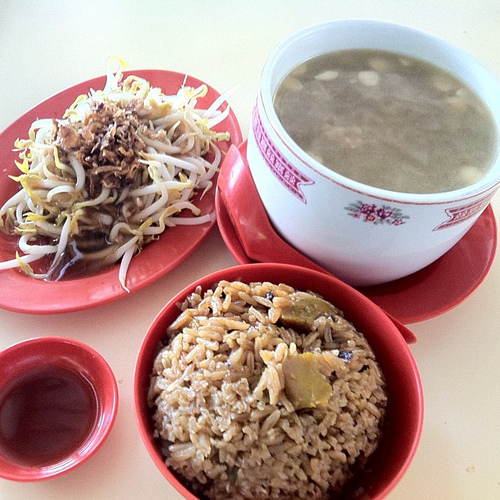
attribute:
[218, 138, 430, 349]
spoon — red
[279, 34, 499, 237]
soup — brown, brothy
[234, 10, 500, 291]
bowl — white, purple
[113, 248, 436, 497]
bowl — red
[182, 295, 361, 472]
rice — brown, light brown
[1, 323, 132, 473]
bowl — small, red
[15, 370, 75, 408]
sauce — red, brown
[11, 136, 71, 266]
noodles — white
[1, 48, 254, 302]
plate — red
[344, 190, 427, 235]
flowers — red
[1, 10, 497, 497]
table — white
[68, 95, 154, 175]
meat — brown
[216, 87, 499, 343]
bowl — red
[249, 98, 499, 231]
markings — red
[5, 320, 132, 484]
dish — small, red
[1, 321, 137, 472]
cup — red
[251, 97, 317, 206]
charcters — asian, red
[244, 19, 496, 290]
cup — white, large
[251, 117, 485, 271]
designs — red, dark red